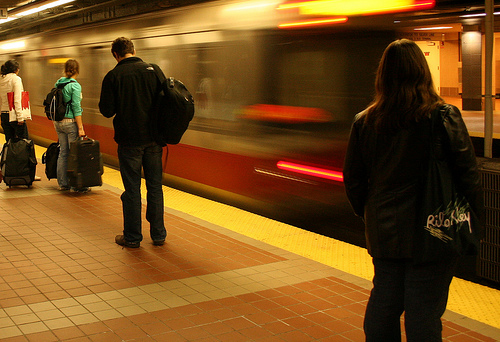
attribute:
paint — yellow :
[212, 270, 242, 284]